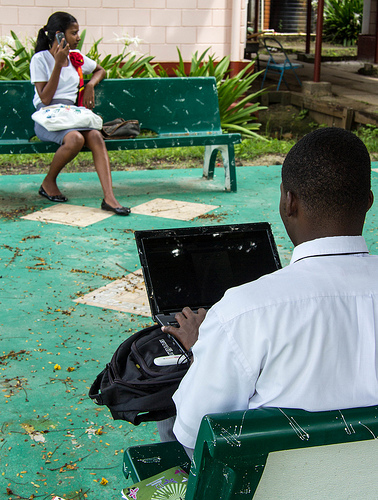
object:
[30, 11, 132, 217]
woman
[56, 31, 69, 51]
phone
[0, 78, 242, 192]
bench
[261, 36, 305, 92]
chair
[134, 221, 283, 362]
laptop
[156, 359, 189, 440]
lap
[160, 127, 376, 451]
man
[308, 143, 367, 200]
back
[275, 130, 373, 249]
head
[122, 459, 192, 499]
book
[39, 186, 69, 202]
shoe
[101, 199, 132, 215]
shoe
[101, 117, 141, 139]
bag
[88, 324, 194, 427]
backpack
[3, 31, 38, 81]
bush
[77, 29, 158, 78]
bush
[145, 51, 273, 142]
bush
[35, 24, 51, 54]
ponytail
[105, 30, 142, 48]
flower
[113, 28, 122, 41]
petals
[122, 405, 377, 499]
bench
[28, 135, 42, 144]
hole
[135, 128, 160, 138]
hole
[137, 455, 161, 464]
scratch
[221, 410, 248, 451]
scratch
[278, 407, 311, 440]
scratch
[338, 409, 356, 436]
scratch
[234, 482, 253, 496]
scratch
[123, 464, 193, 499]
cover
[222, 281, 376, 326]
seam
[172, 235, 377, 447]
shirt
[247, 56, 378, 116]
porch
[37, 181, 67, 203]
foot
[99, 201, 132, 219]
foot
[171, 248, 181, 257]
spot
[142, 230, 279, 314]
screen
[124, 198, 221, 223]
tile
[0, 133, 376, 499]
ground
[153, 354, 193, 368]
jump drive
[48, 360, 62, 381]
debris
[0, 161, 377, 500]
pathway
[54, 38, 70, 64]
hand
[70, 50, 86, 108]
ribbon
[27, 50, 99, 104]
shirt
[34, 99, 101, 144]
skirt